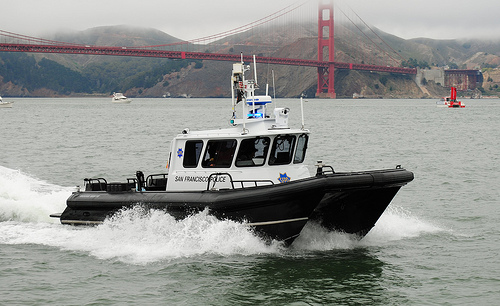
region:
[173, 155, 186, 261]
Black and white boat in the water.Black and white boat in the water.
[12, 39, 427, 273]
this is a ship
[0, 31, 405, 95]
this is a bridge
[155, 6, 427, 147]
this is a mountain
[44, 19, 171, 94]
this is a mountain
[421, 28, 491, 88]
this is a mountain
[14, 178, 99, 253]
this is a wave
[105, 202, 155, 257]
this is a wave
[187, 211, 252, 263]
this is a wave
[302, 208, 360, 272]
this is a wave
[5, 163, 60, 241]
this is a wave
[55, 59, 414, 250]
black and white police boat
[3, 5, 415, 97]
Golden Gate bridge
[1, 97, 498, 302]
dark waters of San Francisco Bay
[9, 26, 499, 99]
mountains in background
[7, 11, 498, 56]
fog on the top of the mountains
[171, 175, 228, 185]
San Francisco police in black letters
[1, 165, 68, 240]
wake behind the police boat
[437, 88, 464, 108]
red boat on the right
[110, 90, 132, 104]
white boat under the bridge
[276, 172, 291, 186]
blue star on the police boat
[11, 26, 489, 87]
red bridge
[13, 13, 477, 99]
bridge is over the water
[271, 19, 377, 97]
bridge next to a hill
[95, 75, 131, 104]
boat under the bridge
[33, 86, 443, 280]
Police boat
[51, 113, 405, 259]
boat is moving in the water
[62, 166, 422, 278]
black at the bottom half of boat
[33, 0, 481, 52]
fog in the sky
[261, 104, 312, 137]
camera on the boat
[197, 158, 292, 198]
railing on the boat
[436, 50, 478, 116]
this is a hut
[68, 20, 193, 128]
this is a mountain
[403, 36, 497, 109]
this is a mountain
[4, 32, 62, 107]
this is a mountain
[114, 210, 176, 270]
this is a wave